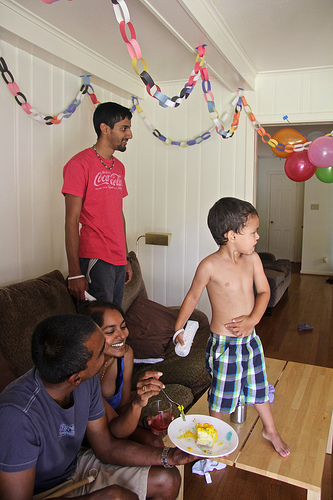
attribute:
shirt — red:
[52, 140, 140, 270]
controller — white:
[172, 318, 201, 357]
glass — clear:
[145, 396, 176, 441]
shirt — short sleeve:
[58, 141, 129, 267]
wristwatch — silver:
[158, 445, 169, 472]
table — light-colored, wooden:
[160, 346, 331, 498]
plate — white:
[166, 412, 240, 460]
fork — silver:
[158, 385, 187, 423]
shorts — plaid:
[202, 328, 270, 413]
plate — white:
[197, 443, 258, 459]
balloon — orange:
[266, 125, 307, 154]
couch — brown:
[23, 291, 40, 305]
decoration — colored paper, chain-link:
[277, 122, 323, 184]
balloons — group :
[268, 125, 332, 186]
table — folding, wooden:
[185, 343, 331, 483]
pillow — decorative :
[126, 300, 180, 356]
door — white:
[260, 144, 308, 269]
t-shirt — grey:
[5, 380, 76, 473]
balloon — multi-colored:
[271, 128, 307, 155]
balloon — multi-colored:
[282, 149, 316, 181]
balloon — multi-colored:
[308, 135, 331, 164]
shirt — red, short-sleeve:
[66, 137, 154, 279]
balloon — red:
[274, 140, 328, 185]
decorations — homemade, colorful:
[0, 4, 327, 156]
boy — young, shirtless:
[171, 193, 290, 461]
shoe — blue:
[294, 324, 312, 335]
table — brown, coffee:
[168, 334, 332, 491]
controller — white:
[165, 313, 213, 364]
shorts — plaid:
[204, 329, 276, 415]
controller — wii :
[174, 317, 203, 355]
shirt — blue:
[2, 366, 107, 488]